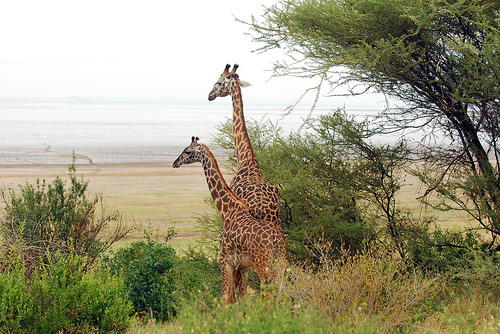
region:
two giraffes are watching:
[159, 62, 314, 329]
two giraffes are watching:
[155, 44, 314, 292]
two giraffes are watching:
[162, 47, 322, 329]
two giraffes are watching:
[174, 54, 328, 276]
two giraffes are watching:
[160, 38, 300, 295]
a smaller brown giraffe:
[173, 140, 302, 316]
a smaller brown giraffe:
[157, 138, 303, 313]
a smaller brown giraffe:
[149, 127, 311, 332]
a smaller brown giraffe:
[163, 122, 293, 306]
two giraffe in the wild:
[24, 28, 346, 304]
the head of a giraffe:
[199, 56, 256, 105]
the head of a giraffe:
[162, 131, 214, 173]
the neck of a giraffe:
[228, 91, 253, 161]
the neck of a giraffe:
[203, 156, 231, 211]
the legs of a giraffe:
[216, 256, 287, 307]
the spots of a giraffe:
[228, 219, 261, 256]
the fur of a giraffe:
[228, 219, 258, 254]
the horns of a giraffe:
[222, 59, 239, 72]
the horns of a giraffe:
[185, 131, 201, 143]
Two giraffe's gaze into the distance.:
[169, 48, 263, 188]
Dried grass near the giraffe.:
[296, 246, 426, 308]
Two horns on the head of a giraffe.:
[202, 47, 253, 106]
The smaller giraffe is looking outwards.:
[168, 134, 294, 302]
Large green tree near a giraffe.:
[250, 2, 488, 102]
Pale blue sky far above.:
[68, 21, 201, 99]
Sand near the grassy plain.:
[50, 163, 159, 206]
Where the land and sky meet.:
[82, 76, 189, 119]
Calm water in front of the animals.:
[43, 115, 165, 166]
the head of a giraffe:
[206, 60, 251, 104]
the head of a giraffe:
[166, 129, 213, 172]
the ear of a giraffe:
[237, 74, 255, 91]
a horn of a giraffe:
[222, 61, 234, 76]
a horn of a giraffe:
[231, 58, 241, 75]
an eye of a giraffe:
[181, 145, 193, 159]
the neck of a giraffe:
[198, 151, 226, 208]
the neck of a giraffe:
[228, 92, 260, 167]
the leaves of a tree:
[122, 244, 169, 296]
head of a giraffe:
[195, 60, 256, 100]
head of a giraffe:
[165, 125, 217, 176]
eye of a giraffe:
[179, 150, 194, 159]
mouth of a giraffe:
[172, 155, 186, 166]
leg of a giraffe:
[193, 238, 251, 313]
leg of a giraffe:
[251, 273, 282, 326]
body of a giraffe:
[218, 176, 285, 233]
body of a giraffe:
[210, 208, 290, 279]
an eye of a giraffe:
[215, 77, 228, 84]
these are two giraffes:
[109, 78, 354, 260]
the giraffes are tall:
[163, 85, 323, 260]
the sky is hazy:
[53, 103, 110, 152]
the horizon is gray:
[45, 95, 203, 203]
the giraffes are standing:
[172, 60, 285, 310]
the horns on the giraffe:
[172, 135, 285, 312]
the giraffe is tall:
[207, 63, 287, 292]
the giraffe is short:
[173, 135, 276, 308]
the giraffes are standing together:
[173, 63, 287, 304]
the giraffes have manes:
[171, 63, 283, 311]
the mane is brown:
[198, 143, 248, 209]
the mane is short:
[202, 141, 247, 211]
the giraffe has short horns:
[174, 136, 286, 316]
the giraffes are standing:
[171, 63, 288, 315]